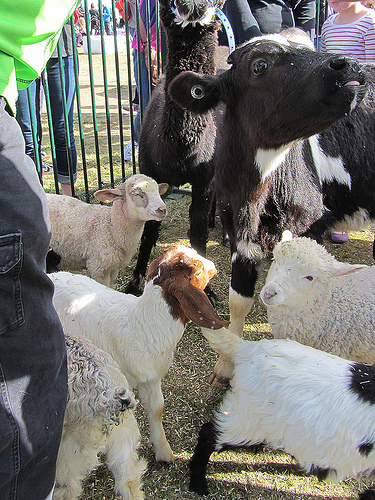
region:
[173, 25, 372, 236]
a black and white calf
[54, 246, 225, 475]
a brown and white goat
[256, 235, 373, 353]
a white lamb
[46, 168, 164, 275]
a gray and cream lamb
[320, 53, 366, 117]
a nose on a calf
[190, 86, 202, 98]
a tag in a calfs ear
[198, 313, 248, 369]
a tail of a goat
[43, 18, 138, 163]
a green iron gate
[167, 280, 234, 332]
a brown ear of a goat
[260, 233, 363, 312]
the head of a lamb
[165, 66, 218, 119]
tag in black furry ear of sheep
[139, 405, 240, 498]
feet of sheep in sawdust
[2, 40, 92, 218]
cropped and cuffed jeans on woman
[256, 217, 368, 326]
face of white furry baby lamb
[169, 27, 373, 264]
black and white goat with tongue sticking out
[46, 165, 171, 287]
baby lamb with dark patch around eye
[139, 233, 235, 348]
head of brown and white goat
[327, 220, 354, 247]
foot in purple shoe under goat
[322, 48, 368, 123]
tongue hanging out under black nose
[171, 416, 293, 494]
shadows of animals being cast on ground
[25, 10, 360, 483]
photo taken at a petting zoo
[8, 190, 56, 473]
person wearing blue jeans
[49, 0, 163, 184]
metal green gate to keep animals in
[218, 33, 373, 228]
black and white baby cow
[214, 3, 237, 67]
tage around animals necl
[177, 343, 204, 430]
ground covered with small leaves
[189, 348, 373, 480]
small black and white animal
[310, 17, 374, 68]
child wearing a white shirt with red stripes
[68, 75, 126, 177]
shadows of people on the ground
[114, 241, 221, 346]
brown and white animal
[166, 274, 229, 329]
Long brown ear on a brown and white goat.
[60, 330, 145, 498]
The white and black fur of the back end of an animal by a person in jeans.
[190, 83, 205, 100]
A round tag in a black and white cows ear.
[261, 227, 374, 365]
A pure white sheep beside a black and white cow.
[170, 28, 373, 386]
A black and white cow with a tongue visible.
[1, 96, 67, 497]
A black pair of jeans on a person in a green shirt.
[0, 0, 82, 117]
A bright green shirt on a black pants man.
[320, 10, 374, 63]
A red and white striped shirt on a girl.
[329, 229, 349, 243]
The tip of a purple shoe under a cow.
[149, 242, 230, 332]
Brown and white head of a sheep.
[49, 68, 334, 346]
Goats in a pen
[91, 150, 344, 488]
Goats in a pen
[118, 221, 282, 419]
Goats in a pen